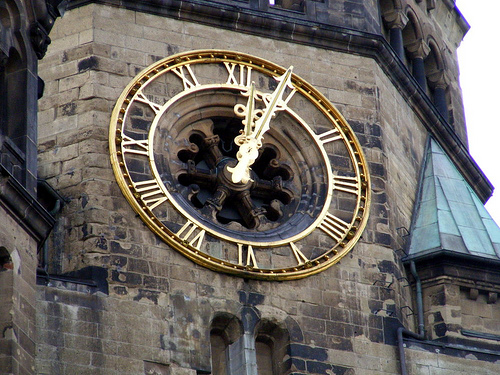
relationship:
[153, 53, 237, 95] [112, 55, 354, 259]
numeral on clock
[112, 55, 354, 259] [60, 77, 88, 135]
clock on building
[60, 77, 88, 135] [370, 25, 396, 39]
building has bricks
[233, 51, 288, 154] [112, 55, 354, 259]
hands of clock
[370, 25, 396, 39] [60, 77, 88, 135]
bricks on building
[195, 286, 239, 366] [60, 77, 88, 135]
arches of building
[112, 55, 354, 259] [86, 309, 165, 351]
clock on wall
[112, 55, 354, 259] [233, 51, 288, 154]
clock has hands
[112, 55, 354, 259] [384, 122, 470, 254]
clock on roof